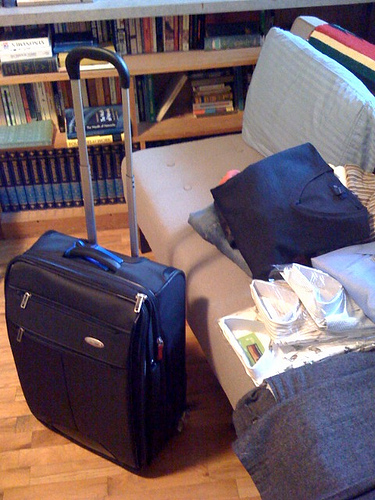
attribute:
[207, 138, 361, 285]
sweater — top, black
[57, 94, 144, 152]
books — arranged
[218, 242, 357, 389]
shirts — group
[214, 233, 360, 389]
shirts — series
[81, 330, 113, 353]
bag — logo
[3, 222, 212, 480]
bag — small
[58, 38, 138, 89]
part — black, top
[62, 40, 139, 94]
handle — black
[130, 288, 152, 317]
zipper — silver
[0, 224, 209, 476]
case — suit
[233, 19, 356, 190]
pillow — white, blue, striped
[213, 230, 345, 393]
shirts — white, folded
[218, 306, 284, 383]
collar — white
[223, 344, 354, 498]
pants — folded, gray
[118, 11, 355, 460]
couch — grey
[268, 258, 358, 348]
shirt — packaged, white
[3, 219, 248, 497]
floor — light, brown, hardwood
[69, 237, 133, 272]
tag — blue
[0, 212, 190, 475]
suitcase — black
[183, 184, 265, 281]
pillowcase — grey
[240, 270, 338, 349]
shirt — folded, striped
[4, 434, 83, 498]
flooring — wood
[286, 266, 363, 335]
shirt — white, collared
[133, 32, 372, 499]
sofa — gray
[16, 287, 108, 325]
zipper — metal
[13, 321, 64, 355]
zipper — metal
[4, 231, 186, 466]
bag — packed, black, colored